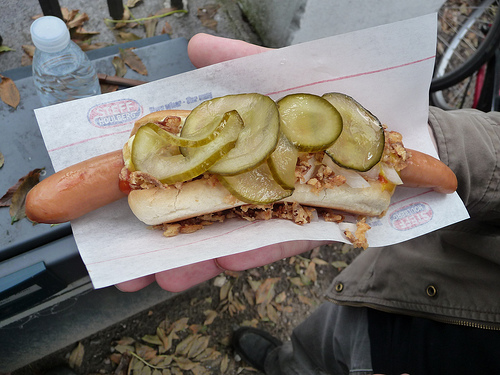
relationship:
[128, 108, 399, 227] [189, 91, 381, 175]
bun beneath cucumbers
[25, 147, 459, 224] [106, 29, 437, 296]
hot dog in hand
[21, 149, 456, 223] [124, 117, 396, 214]
hot dog with a bun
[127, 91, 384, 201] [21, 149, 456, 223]
pickles on hot dog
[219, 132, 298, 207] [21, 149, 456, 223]
pickles on hot dog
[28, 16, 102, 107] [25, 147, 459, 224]
water bottle near hot dog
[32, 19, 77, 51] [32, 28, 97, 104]
cap on bottle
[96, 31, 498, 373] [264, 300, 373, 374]
person wearing pants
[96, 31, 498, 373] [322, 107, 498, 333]
person wearing jacket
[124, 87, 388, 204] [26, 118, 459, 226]
pickels on hot dog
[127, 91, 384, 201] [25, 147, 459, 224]
pickles garnish hot dog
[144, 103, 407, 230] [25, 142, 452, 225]
toppings on hot dog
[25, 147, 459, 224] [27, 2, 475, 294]
hot dog on paper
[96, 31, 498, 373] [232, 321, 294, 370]
person wearing black shoes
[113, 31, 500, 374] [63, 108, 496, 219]
person holding hot dog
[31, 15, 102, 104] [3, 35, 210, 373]
water on table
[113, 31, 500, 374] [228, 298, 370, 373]
person wearing pants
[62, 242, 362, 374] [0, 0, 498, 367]
leaves on ground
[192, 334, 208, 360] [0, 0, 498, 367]
leaves on ground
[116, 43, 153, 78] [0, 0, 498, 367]
leaves on ground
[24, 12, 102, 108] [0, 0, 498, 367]
water bottle on ground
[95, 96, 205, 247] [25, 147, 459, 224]
paper with hot dog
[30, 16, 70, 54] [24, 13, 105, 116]
cap on bottle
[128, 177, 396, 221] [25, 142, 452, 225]
bun on hot dog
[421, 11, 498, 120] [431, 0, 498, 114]
wheels on bike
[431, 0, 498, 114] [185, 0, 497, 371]
bike next to person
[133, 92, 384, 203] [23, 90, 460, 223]
cucumbers on hot dog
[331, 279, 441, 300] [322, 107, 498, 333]
buttons on jacket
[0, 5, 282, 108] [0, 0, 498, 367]
leaves on ground